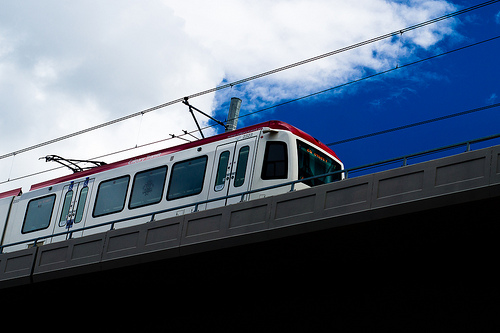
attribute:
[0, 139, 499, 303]
wall — cement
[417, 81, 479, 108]
sky — dark blue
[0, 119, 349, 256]
train — metal, red, white, elevated, runs on, electric, red and white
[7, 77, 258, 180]
cable — electric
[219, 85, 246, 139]
pole — metal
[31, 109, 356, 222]
train — white, red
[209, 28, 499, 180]
sky — blue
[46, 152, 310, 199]
train — commuter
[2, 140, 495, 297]
stone — gray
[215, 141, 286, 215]
doors — double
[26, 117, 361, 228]
train — white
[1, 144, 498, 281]
bridge — stone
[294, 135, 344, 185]
windshield — of the train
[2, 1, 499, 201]
sky — blue, partly cloudy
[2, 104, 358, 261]
train — white, red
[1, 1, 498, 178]
sky — dark, blue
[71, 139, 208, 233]
panes — clear, window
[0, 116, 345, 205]
roof — red